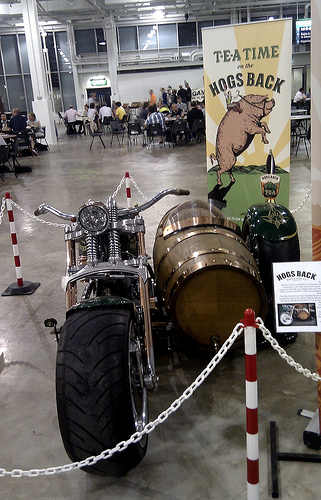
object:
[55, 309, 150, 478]
tire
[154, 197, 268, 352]
barrel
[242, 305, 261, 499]
pole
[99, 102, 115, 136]
people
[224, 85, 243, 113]
man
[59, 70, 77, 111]
windows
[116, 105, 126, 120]
shirt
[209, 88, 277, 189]
drawing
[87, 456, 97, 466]
chains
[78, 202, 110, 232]
headlight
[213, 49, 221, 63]
letters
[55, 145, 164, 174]
floor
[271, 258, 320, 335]
sign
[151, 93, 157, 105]
shirt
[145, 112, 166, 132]
shirt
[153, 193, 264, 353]
sidecar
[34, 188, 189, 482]
motorcycle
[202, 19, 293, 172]
advertisement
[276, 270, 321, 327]
information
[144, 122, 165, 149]
chair